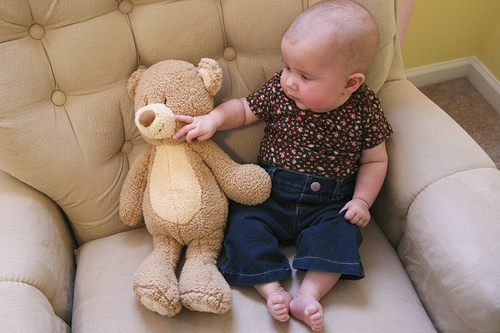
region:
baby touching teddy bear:
[170, 1, 394, 330]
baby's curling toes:
[264, 291, 323, 331]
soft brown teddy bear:
[114, 53, 273, 318]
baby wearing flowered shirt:
[168, 1, 392, 332]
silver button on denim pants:
[300, 173, 330, 196]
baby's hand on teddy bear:
[168, 108, 221, 148]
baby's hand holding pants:
[335, 197, 375, 229]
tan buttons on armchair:
[21, 2, 237, 160]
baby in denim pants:
[163, 0, 393, 332]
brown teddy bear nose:
[133, 106, 159, 126]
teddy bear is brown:
[62, 52, 228, 324]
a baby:
[190, 9, 403, 331]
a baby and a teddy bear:
[100, 2, 457, 331]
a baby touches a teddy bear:
[92, 6, 481, 330]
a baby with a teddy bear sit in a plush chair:
[10, 4, 487, 330]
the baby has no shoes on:
[217, 9, 414, 331]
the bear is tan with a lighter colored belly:
[101, 40, 311, 331]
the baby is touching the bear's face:
[209, 1, 459, 328]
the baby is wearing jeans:
[223, 0, 440, 329]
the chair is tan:
[11, 5, 489, 330]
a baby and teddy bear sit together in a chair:
[89, 7, 440, 326]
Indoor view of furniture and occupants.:
[7, 10, 498, 328]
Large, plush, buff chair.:
[10, 13, 498, 331]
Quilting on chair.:
[14, 15, 109, 165]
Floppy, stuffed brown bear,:
[125, 54, 258, 322]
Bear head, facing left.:
[122, 62, 221, 155]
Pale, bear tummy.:
[152, 151, 204, 227]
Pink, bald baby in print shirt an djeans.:
[223, 8, 397, 329]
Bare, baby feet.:
[257, 272, 346, 329]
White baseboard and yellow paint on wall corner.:
[399, 7, 491, 101]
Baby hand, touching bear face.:
[161, 103, 237, 154]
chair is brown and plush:
[56, 112, 282, 314]